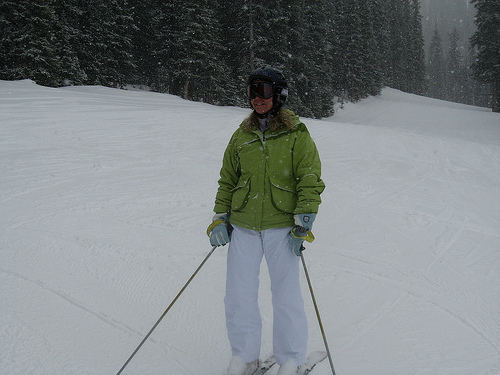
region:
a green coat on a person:
[204, 106, 334, 224]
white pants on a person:
[216, 224, 323, 360]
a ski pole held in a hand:
[112, 220, 236, 374]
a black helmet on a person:
[243, 61, 298, 119]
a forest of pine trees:
[4, 2, 433, 118]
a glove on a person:
[193, 205, 238, 255]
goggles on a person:
[241, 78, 303, 104]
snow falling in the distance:
[420, 7, 498, 97]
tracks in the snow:
[352, 192, 491, 353]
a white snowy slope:
[3, 88, 494, 369]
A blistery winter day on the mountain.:
[18, 6, 487, 368]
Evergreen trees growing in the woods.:
[7, 5, 232, 107]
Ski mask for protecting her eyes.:
[239, 77, 279, 102]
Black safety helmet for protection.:
[237, 62, 294, 109]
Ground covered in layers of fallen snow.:
[360, 116, 490, 348]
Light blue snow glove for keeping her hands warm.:
[198, 207, 235, 247]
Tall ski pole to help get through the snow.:
[291, 244, 346, 373]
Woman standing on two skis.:
[195, 56, 352, 373]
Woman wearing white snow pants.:
[215, 218, 318, 373]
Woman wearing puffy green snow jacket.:
[207, 66, 329, 240]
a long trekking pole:
[301, 251, 346, 373]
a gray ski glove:
[210, 215, 232, 247]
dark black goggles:
[242, 83, 275, 98]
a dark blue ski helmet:
[245, 66, 290, 106]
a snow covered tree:
[429, 19, 452, 96]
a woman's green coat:
[211, 108, 327, 229]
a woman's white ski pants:
[220, 220, 306, 368]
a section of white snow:
[310, 67, 499, 140]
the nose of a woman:
[250, 97, 265, 103]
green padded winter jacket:
[221, 113, 323, 230]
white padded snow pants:
[222, 226, 309, 365]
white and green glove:
[205, 214, 235, 248]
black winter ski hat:
[248, 68, 291, 109]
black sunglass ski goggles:
[246, 82, 274, 99]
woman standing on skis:
[198, 66, 328, 373]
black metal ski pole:
[114, 233, 229, 370]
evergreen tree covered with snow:
[14, 1, 88, 86]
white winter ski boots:
[226, 351, 310, 373]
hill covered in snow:
[6, 80, 496, 373]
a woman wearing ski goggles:
[196, 58, 327, 130]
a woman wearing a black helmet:
[226, 62, 322, 146]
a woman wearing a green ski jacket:
[225, 72, 340, 244]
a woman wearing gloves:
[197, 66, 367, 294]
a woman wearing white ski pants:
[194, 77, 354, 367]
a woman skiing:
[158, 69, 348, 370]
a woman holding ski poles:
[145, 67, 410, 370]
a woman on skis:
[165, 70, 333, 372]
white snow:
[317, 104, 492, 366]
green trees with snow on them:
[3, 14, 421, 113]